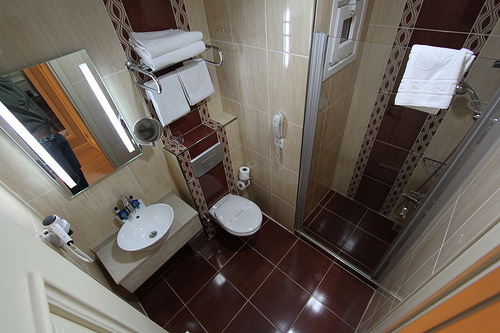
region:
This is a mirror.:
[10, 60, 127, 200]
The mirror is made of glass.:
[15, 55, 120, 185]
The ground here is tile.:
[177, 261, 359, 331]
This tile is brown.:
[181, 256, 336, 331]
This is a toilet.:
[219, 193, 281, 242]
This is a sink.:
[103, 194, 181, 254]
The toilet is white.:
[213, 185, 273, 235]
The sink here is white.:
[115, 208, 170, 244]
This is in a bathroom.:
[78, 64, 440, 330]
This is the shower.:
[324, 53, 427, 275]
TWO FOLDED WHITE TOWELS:
[126, 24, 210, 75]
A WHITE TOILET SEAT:
[210, 195, 266, 238]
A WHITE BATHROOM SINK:
[110, 190, 176, 253]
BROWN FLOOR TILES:
[192, 252, 354, 324]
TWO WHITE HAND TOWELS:
[141, 57, 216, 127]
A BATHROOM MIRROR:
[0, 45, 146, 197]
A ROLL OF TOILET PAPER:
[235, 163, 255, 181]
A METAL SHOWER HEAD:
[451, 73, 487, 116]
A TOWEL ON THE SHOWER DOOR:
[390, 38, 477, 118]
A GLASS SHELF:
[160, 108, 244, 159]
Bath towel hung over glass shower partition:
[392, 42, 476, 117]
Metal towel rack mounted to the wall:
[123, 42, 224, 96]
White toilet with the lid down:
[206, 190, 264, 238]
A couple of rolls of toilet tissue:
[234, 164, 251, 191]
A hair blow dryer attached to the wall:
[38, 213, 93, 265]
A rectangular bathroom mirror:
[0, 47, 144, 199]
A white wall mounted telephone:
[270, 110, 287, 167]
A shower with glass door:
[291, 30, 498, 292]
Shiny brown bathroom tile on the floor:
[132, 188, 404, 332]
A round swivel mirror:
[131, 116, 165, 149]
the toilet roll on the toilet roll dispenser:
[238, 164, 250, 179]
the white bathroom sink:
[113, 199, 173, 251]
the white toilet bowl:
[210, 191, 263, 234]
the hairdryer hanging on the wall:
[39, 211, 93, 262]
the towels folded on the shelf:
[128, 28, 207, 73]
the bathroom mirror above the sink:
[0, 48, 144, 198]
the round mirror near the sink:
[133, 116, 163, 150]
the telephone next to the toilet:
[273, 111, 285, 166]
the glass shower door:
[294, 32, 499, 277]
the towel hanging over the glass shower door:
[394, 43, 474, 115]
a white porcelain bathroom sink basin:
[115, 197, 175, 252]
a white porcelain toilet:
[210, 191, 263, 236]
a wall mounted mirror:
[7, 48, 146, 198]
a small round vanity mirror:
[132, 117, 162, 144]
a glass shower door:
[297, 25, 499, 277]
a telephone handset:
[269, 111, 287, 168]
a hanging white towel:
[391, 41, 476, 119]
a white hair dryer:
[39, 211, 93, 263]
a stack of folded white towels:
[123, 26, 208, 70]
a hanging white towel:
[142, 73, 192, 126]